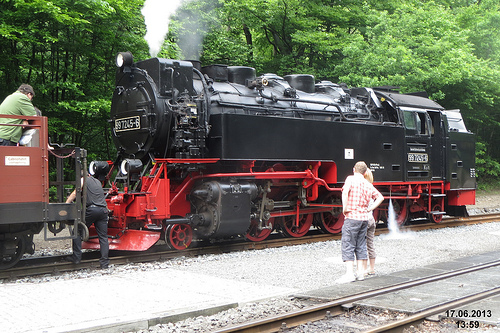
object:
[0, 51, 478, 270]
train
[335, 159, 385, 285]
couple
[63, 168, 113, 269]
man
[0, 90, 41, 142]
shirt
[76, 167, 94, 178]
baseball hat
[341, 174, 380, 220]
shirt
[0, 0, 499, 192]
forest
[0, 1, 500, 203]
background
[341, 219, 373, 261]
pants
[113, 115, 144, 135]
numbers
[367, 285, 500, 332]
rail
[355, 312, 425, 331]
part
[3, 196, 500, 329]
ground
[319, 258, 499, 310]
part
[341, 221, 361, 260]
part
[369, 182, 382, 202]
part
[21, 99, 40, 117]
part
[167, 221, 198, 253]
wheel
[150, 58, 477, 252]
side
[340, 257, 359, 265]
edge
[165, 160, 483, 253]
edge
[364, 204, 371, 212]
hand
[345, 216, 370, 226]
hip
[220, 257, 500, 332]
tracks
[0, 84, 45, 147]
man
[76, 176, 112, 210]
shirt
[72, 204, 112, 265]
pants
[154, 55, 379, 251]
engine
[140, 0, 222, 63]
steam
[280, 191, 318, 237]
wheel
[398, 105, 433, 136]
window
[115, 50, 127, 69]
light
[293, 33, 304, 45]
leaf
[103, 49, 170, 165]
end of train